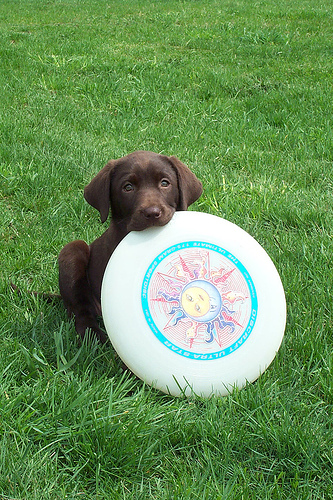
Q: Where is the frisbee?
A: Puppy's mouth.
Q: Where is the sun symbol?
A: On frisbee.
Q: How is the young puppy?
A: Brown.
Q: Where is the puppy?
A: On grass.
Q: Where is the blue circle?
A: Around the symbol.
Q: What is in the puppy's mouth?
A: A frisbee.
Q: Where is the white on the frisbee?
A: The edge.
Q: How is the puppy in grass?
A: Laying.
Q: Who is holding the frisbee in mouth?
A: The puppy.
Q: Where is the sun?
A: On frisbee.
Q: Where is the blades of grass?
A: In the field.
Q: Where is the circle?
A: Middle of frisbee.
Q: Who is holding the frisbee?
A: Puppy.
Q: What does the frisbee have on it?
A: Sun.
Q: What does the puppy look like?
A: Proud.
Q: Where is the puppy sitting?
A: On the grass.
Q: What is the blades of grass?
A: Thick.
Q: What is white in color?
A: Frisbee.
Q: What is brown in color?
A: Puppy.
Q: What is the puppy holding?
A: Frisbee.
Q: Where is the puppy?
A: In the field.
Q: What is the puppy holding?
A: Frisbee.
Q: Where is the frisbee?
A: Dogs mouth.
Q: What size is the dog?
A: Small.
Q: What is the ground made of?
A: Grass.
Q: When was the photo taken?
A: Morning.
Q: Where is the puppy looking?
A: Forward.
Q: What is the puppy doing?
A: Sitting.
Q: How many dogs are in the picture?
A: One.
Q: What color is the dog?
A: Brown.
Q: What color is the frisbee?
A: White.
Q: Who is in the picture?
A: No one.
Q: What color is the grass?
A: Green.